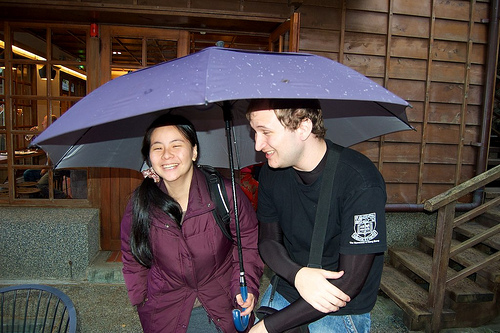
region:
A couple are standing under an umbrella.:
[31, 40, 411, 332]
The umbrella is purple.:
[32, 44, 416, 179]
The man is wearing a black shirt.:
[256, 142, 389, 316]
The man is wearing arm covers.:
[251, 215, 384, 332]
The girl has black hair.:
[127, 110, 202, 262]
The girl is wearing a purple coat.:
[123, 168, 255, 331]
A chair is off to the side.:
[0, 275, 81, 331]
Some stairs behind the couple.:
[378, 158, 498, 326]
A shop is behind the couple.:
[0, 5, 302, 280]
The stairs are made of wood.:
[376, 159, 498, 331]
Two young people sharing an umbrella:
[27, 40, 432, 321]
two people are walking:
[93, 74, 363, 330]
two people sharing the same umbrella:
[142, 60, 361, 330]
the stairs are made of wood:
[410, 170, 499, 282]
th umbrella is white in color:
[139, 28, 349, 108]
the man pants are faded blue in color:
[273, 291, 345, 332]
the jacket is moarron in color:
[109, 222, 239, 327]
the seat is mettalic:
[9, 269, 82, 331]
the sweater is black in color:
[259, 166, 396, 286]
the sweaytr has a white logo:
[279, 182, 402, 283]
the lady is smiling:
[140, 113, 246, 268]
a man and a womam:
[120, 92, 383, 331]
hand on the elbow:
[284, 260, 374, 317]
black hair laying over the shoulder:
[118, 155, 193, 276]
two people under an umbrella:
[33, 24, 432, 330]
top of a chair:
[2, 278, 91, 330]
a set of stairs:
[381, 160, 498, 330]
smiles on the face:
[156, 163, 182, 171]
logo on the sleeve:
[346, 206, 385, 249]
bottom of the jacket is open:
[161, 290, 241, 331]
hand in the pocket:
[126, 290, 155, 322]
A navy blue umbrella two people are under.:
[28, 38, 418, 168]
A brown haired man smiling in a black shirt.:
[244, 103, 386, 332]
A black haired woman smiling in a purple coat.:
[123, 110, 263, 332]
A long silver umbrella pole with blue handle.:
[220, 101, 250, 332]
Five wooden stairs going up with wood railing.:
[374, 162, 498, 332]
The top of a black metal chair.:
[1, 283, 78, 332]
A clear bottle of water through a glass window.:
[24, 125, 36, 140]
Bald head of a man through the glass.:
[38, 113, 55, 129]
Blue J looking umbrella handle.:
[230, 282, 252, 331]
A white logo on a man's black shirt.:
[351, 212, 378, 241]